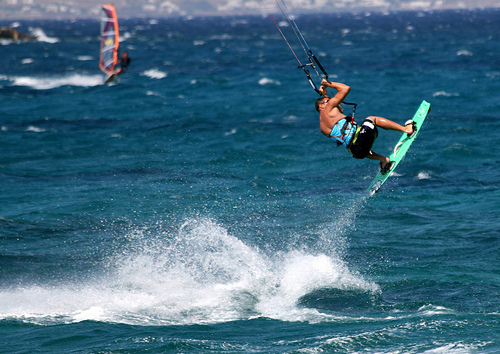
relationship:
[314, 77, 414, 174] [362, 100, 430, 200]
guy with surf board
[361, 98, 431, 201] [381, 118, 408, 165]
surfboard with feet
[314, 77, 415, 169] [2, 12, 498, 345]
guy in water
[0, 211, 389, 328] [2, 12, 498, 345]
waves in water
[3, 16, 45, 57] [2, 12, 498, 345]
mountain behind water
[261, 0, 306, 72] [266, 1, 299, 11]
kite string of a kite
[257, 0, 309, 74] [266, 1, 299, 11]
kite string of a kite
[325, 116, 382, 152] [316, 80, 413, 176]
suit of man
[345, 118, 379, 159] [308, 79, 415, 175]
suit of man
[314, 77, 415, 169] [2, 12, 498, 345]
guy jumping out of water